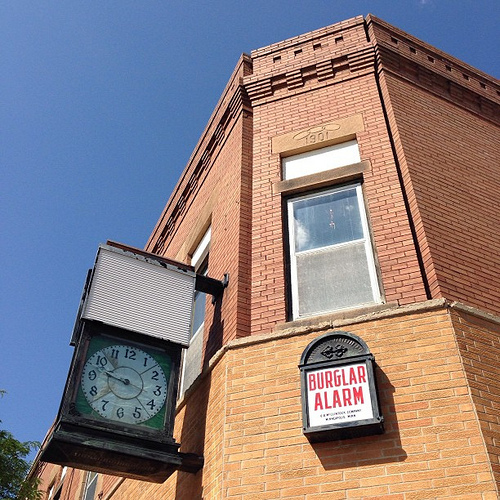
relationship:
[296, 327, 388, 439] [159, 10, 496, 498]
alarm sign on building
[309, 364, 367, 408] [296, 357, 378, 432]
letters on a sign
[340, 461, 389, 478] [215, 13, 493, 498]
brick on wall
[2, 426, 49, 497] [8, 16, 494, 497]
tree limbs near building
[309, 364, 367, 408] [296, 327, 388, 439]
letters on alarm sign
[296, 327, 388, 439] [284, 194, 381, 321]
alarm sign below window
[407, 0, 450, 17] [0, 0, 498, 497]
clouds in sky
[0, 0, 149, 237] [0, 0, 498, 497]
clouds in sky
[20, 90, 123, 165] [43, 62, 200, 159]
clouds in sky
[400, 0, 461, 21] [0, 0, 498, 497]
white clouds in sky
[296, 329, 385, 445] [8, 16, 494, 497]
alarm sign on building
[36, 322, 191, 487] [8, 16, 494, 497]
clock on building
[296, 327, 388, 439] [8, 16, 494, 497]
alarm sign on building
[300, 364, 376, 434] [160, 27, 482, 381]
burglar alarm on building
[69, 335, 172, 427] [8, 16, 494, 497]
clock on building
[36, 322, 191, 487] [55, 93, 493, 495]
clock on building